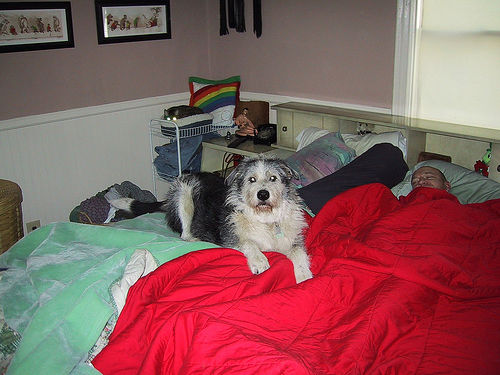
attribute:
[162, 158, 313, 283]
dog — beautiful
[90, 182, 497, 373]
blanket — red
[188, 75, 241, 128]
pillow — rainbow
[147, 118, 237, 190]
baskets — wire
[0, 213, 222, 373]
blanket — green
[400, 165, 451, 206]
man — laying down, lying down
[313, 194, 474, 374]
blanket — red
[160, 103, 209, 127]
cat — fuzzy, gray